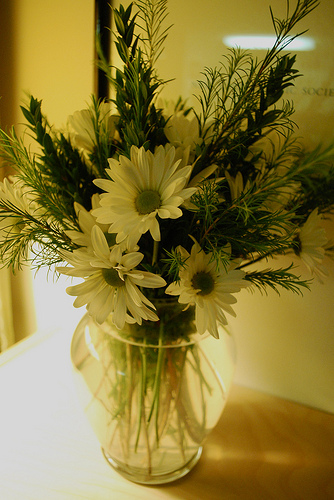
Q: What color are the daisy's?
A: White.